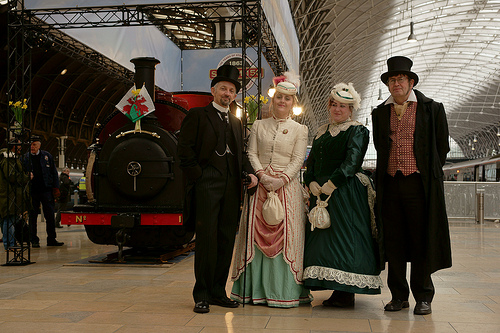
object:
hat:
[381, 56, 419, 87]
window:
[362, 129, 472, 170]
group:
[170, 54, 457, 316]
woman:
[303, 76, 384, 311]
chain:
[214, 147, 228, 157]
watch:
[226, 142, 233, 153]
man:
[372, 56, 452, 316]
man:
[19, 137, 66, 247]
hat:
[331, 82, 363, 110]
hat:
[272, 75, 300, 95]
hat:
[208, 64, 248, 86]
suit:
[176, 103, 247, 304]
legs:
[386, 259, 438, 302]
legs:
[191, 194, 240, 296]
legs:
[27, 203, 57, 244]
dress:
[228, 115, 310, 308]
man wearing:
[176, 56, 451, 314]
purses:
[261, 184, 331, 231]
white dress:
[225, 117, 308, 307]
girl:
[226, 81, 308, 308]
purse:
[262, 188, 287, 226]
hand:
[257, 172, 288, 191]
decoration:
[115, 83, 155, 122]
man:
[179, 65, 259, 317]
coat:
[369, 88, 453, 270]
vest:
[389, 103, 419, 178]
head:
[387, 71, 412, 96]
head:
[328, 96, 351, 120]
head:
[273, 89, 294, 114]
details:
[300, 264, 383, 290]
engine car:
[60, 57, 216, 262]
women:
[226, 78, 386, 307]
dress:
[302, 121, 381, 296]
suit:
[18, 149, 58, 242]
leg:
[193, 197, 222, 303]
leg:
[217, 195, 246, 296]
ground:
[11, 267, 193, 332]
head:
[211, 81, 237, 107]